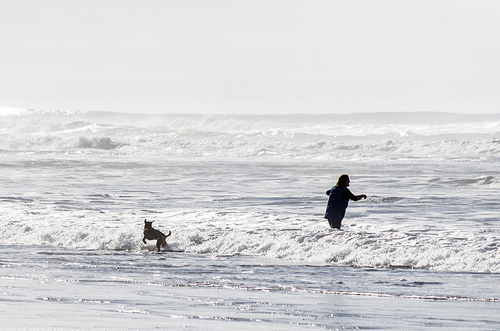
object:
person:
[323, 173, 367, 230]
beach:
[37, 103, 489, 324]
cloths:
[323, 186, 351, 230]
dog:
[141, 218, 173, 252]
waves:
[0, 212, 499, 271]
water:
[0, 105, 500, 330]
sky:
[0, 0, 498, 115]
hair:
[336, 174, 351, 189]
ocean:
[0, 106, 498, 330]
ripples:
[46, 170, 283, 212]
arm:
[349, 192, 366, 202]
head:
[335, 173, 352, 187]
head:
[143, 218, 156, 228]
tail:
[164, 229, 173, 237]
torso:
[328, 185, 347, 217]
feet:
[141, 236, 149, 244]